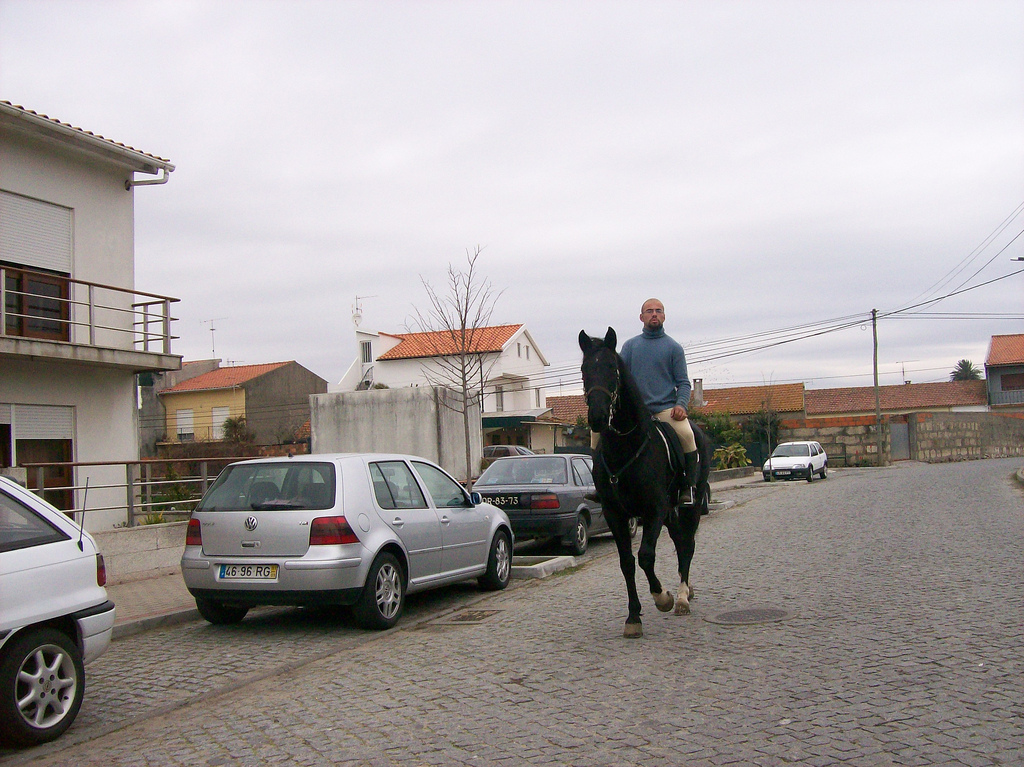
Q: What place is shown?
A: It is a road.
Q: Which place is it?
A: It is a road.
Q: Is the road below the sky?
A: Yes, the road is below the sky.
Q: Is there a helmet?
A: No, there are no helmets.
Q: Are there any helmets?
A: No, there are no helmets.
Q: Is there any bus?
A: No, there are no buses.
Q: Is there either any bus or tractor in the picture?
A: No, there are no buses or tractors.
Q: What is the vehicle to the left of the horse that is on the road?
A: The vehicle is a car.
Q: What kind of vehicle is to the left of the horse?
A: The vehicle is a car.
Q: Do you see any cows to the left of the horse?
A: No, there is a car to the left of the horse.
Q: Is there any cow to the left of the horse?
A: No, there is a car to the left of the horse.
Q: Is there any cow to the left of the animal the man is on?
A: No, there is a car to the left of the horse.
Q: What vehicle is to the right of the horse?
A: The vehicle is a car.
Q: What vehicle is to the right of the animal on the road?
A: The vehicle is a car.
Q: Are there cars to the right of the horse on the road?
A: Yes, there is a car to the right of the horse.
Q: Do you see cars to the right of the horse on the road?
A: Yes, there is a car to the right of the horse.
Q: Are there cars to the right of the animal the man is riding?
A: Yes, there is a car to the right of the horse.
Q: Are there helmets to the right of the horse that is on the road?
A: No, there is a car to the right of the horse.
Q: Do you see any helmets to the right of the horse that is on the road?
A: No, there is a car to the right of the horse.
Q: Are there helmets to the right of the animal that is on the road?
A: No, there is a car to the right of the horse.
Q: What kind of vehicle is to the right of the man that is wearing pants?
A: The vehicle is a car.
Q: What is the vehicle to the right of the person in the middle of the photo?
A: The vehicle is a car.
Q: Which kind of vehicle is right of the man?
A: The vehicle is a car.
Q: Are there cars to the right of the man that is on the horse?
A: Yes, there is a car to the right of the man.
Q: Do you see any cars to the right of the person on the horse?
A: Yes, there is a car to the right of the man.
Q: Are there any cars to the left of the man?
A: No, the car is to the right of the man.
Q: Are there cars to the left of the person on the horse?
A: No, the car is to the right of the man.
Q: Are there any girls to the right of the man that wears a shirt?
A: No, there is a car to the right of the man.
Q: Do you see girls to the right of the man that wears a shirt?
A: No, there is a car to the right of the man.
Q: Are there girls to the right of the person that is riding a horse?
A: No, there is a car to the right of the man.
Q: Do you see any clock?
A: No, there are no clocks.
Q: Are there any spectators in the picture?
A: No, there are no spectators.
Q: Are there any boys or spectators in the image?
A: No, there are no spectators or boys.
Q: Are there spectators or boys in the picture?
A: No, there are no spectators or boys.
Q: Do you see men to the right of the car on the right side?
A: No, the man is to the left of the car.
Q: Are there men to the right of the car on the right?
A: No, the man is to the left of the car.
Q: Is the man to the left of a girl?
A: No, the man is to the left of the car.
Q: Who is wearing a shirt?
A: The man is wearing a shirt.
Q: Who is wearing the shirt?
A: The man is wearing a shirt.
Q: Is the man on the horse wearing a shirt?
A: Yes, the man is wearing a shirt.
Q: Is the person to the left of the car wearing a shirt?
A: Yes, the man is wearing a shirt.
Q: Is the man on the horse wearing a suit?
A: No, the man is wearing a shirt.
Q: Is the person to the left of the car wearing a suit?
A: No, the man is wearing a shirt.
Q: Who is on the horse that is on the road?
A: The man is on the horse.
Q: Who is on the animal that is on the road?
A: The man is on the horse.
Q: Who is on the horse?
A: The man is on the horse.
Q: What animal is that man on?
A: The man is on the horse.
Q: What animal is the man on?
A: The man is on the horse.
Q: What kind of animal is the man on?
A: The man is on the horse.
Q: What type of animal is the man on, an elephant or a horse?
A: The man is on a horse.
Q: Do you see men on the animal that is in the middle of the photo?
A: Yes, there is a man on the horse.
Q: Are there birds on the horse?
A: No, there is a man on the horse.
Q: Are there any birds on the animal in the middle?
A: No, there is a man on the horse.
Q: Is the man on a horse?
A: Yes, the man is on a horse.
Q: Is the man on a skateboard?
A: No, the man is on a horse.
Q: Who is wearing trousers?
A: The man is wearing trousers.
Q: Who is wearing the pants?
A: The man is wearing trousers.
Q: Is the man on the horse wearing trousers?
A: Yes, the man is wearing trousers.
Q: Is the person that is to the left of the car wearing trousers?
A: Yes, the man is wearing trousers.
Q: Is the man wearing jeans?
A: No, the man is wearing trousers.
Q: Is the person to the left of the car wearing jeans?
A: No, the man is wearing trousers.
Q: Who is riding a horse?
A: The man is riding a horse.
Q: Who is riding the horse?
A: The man is riding a horse.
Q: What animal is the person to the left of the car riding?
A: The man is riding a horse.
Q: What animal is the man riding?
A: The man is riding a horse.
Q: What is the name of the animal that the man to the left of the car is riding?
A: The animal is a horse.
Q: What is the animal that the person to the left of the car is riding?
A: The animal is a horse.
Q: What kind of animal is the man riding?
A: The man is riding a horse.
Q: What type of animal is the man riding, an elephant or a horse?
A: The man is riding a horse.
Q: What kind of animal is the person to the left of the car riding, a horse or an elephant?
A: The man is riding a horse.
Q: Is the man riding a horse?
A: Yes, the man is riding a horse.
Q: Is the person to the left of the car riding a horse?
A: Yes, the man is riding a horse.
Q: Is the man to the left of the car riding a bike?
A: No, the man is riding a horse.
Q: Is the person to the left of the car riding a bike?
A: No, the man is riding a horse.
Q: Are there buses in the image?
A: No, there are no buses.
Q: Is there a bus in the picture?
A: No, there are no buses.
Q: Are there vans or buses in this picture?
A: No, there are no buses or vans.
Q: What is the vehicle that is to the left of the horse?
A: The vehicle is a car.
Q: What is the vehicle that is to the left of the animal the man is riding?
A: The vehicle is a car.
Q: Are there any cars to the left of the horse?
A: Yes, there is a car to the left of the horse.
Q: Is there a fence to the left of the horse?
A: No, there is a car to the left of the horse.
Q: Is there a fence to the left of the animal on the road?
A: No, there is a car to the left of the horse.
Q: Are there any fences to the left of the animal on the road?
A: No, there is a car to the left of the horse.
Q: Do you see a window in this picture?
A: Yes, there is a window.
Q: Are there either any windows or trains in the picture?
A: Yes, there is a window.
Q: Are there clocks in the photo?
A: No, there are no clocks.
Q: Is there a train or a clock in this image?
A: No, there are no clocks or trains.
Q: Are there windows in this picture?
A: Yes, there is a window.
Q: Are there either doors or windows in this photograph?
A: Yes, there is a window.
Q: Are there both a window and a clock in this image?
A: No, there is a window but no clocks.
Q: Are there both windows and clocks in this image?
A: No, there is a window but no clocks.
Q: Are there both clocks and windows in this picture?
A: No, there is a window but no clocks.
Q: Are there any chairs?
A: No, there are no chairs.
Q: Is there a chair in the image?
A: No, there are no chairs.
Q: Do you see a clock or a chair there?
A: No, there are no chairs or clocks.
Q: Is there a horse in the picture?
A: Yes, there is a horse.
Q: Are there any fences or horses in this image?
A: Yes, there is a horse.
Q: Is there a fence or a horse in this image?
A: Yes, there is a horse.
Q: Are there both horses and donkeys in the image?
A: No, there is a horse but no donkeys.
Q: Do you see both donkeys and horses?
A: No, there is a horse but no donkeys.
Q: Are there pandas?
A: No, there are no pandas.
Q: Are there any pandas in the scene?
A: No, there are no pandas.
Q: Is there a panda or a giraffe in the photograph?
A: No, there are no pandas or giraffes.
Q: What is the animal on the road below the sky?
A: The animal is a horse.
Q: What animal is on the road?
A: The animal is a horse.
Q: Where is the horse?
A: The horse is on the road.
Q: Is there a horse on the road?
A: Yes, there is a horse on the road.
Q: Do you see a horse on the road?
A: Yes, there is a horse on the road.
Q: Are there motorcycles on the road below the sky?
A: No, there is a horse on the road.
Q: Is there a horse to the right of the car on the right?
A: No, the horse is to the left of the car.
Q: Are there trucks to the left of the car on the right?
A: No, there is a horse to the left of the car.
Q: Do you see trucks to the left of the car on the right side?
A: No, there is a horse to the left of the car.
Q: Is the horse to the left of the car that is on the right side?
A: Yes, the horse is to the left of the car.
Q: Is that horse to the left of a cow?
A: No, the horse is to the left of the car.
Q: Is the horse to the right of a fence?
A: No, the horse is to the right of the car.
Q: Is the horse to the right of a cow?
A: No, the horse is to the right of the car.